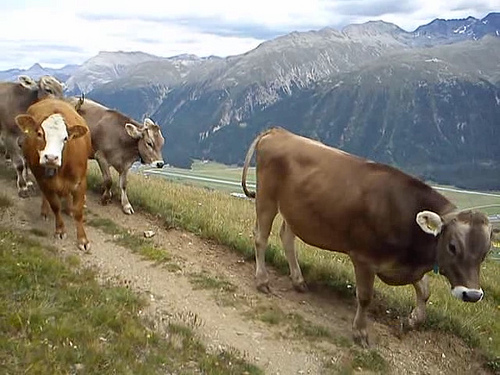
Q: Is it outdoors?
A: Yes, it is outdoors.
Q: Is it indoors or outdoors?
A: It is outdoors.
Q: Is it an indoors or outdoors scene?
A: It is outdoors.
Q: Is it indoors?
A: No, it is outdoors.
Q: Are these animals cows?
A: Yes, all the animals are cows.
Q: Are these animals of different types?
A: No, all the animals are cows.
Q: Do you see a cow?
A: Yes, there is a cow.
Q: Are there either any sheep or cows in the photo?
A: Yes, there is a cow.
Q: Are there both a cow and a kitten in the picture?
A: No, there is a cow but no kittens.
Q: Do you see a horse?
A: No, there are no horses.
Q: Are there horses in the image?
A: No, there are no horses.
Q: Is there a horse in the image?
A: No, there are no horses.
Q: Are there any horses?
A: No, there are no horses.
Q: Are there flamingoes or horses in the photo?
A: No, there are no horses or flamingoes.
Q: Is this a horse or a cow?
A: This is a cow.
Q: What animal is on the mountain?
A: The cow is on the mountain.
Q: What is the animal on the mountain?
A: The animal is a cow.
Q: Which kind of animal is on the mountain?
A: The animal is a cow.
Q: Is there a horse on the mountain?
A: No, there is a cow on the mountain.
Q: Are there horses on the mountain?
A: No, there is a cow on the mountain.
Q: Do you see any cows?
A: Yes, there is a cow.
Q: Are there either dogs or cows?
A: Yes, there is a cow.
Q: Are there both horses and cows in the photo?
A: No, there is a cow but no horses.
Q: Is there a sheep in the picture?
A: No, there is no sheep.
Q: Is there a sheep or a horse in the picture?
A: No, there are no sheep or horses.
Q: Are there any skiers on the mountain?
A: No, there is a cow on the mountain.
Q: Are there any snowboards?
A: No, there are no snowboards.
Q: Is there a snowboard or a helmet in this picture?
A: No, there are no snowboards or helmets.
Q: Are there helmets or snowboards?
A: No, there are no snowboards or helmets.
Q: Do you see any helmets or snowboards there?
A: No, there are no snowboards or helmets.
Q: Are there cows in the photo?
A: Yes, there is a cow.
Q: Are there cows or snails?
A: Yes, there is a cow.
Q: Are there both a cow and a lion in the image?
A: No, there is a cow but no lions.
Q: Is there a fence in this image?
A: No, there are no fences.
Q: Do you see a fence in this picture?
A: No, there are no fences.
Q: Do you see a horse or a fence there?
A: No, there are no fences or horses.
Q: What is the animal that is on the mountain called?
A: The animal is a cow.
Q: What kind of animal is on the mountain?
A: The animal is a cow.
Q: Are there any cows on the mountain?
A: Yes, there is a cow on the mountain.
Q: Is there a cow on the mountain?
A: Yes, there is a cow on the mountain.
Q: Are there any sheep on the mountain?
A: No, there is a cow on the mountain.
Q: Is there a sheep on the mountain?
A: No, there is a cow on the mountain.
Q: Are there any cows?
A: Yes, there is a cow.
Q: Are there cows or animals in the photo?
A: Yes, there is a cow.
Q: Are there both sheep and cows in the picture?
A: No, there is a cow but no sheep.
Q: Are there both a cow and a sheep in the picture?
A: No, there is a cow but no sheep.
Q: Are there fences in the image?
A: No, there are no fences.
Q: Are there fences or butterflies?
A: No, there are no fences or butterflies.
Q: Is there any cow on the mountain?
A: Yes, there is a cow on the mountain.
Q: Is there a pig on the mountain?
A: No, there is a cow on the mountain.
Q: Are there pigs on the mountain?
A: No, there is a cow on the mountain.